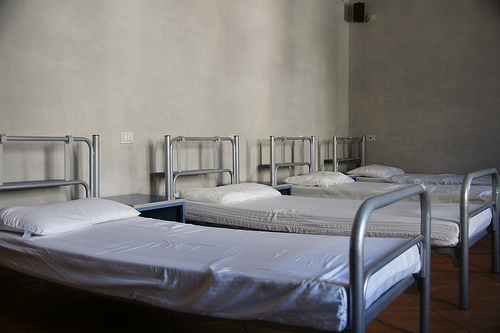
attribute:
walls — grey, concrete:
[0, 2, 493, 172]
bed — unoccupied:
[331, 131, 496, 186]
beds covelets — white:
[5, 106, 497, 328]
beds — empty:
[46, 51, 486, 319]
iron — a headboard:
[321, 160, 444, 295]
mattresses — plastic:
[151, 118, 461, 299]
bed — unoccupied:
[0, 124, 437, 331]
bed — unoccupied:
[330, 132, 498, 201]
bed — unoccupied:
[267, 135, 494, 307]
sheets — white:
[203, 235, 296, 292]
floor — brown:
[414, 279, 487, 325]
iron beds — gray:
[0, 136, 430, 331]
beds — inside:
[50, 91, 494, 311]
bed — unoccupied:
[163, 135, 499, 310]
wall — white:
[0, 0, 498, 214]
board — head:
[158, 130, 246, 197]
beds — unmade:
[0, 135, 498, 331]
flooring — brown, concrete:
[252, 192, 499, 315]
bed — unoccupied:
[268, 131, 491, 203]